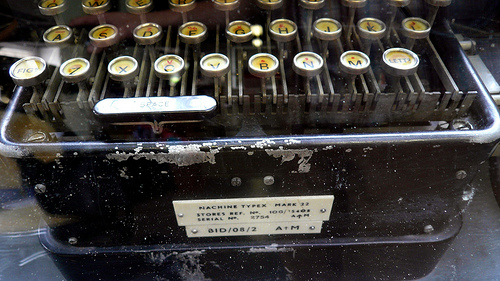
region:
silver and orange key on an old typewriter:
[380, 43, 420, 78]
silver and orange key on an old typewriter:
[339, 45, 369, 78]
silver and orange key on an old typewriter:
[290, 49, 325, 75]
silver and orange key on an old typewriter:
[246, 49, 281, 77]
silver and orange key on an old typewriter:
[196, 49, 234, 81]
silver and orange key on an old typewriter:
[150, 52, 189, 79]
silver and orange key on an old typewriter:
[106, 54, 137, 79]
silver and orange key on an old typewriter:
[56, 53, 91, 82]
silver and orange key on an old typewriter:
[10, 55, 51, 84]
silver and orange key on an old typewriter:
[355, 14, 387, 40]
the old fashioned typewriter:
[0, 0, 498, 278]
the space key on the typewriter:
[90, 95, 217, 120]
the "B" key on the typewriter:
[247, 51, 278, 76]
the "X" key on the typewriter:
[107, 55, 139, 81]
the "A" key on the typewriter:
[43, 26, 72, 48]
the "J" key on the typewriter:
[312, 18, 342, 40]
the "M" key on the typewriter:
[338, 47, 370, 74]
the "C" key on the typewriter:
[154, 55, 185, 77]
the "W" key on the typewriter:
[82, 0, 111, 13]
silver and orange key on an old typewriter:
[85, 20, 119, 48]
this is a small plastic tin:
[376, 39, 419, 81]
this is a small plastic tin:
[331, 43, 376, 86]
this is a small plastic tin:
[243, 45, 286, 89]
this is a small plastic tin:
[153, 47, 203, 96]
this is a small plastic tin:
[56, 45, 97, 87]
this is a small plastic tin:
[4, 47, 54, 105]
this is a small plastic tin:
[86, 21, 124, 44]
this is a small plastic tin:
[179, 15, 211, 45]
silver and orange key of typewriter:
[379, 43, 419, 76]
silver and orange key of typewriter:
[399, 17, 434, 39]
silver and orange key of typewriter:
[355, 13, 389, 43]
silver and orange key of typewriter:
[310, 15, 345, 41]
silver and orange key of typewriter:
[268, 15, 298, 42]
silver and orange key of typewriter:
[224, 17, 256, 44]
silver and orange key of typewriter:
[176, 17, 208, 44]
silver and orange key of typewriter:
[130, 18, 162, 47]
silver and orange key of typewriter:
[85, 21, 122, 45]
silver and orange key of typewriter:
[40, 19, 75, 51]